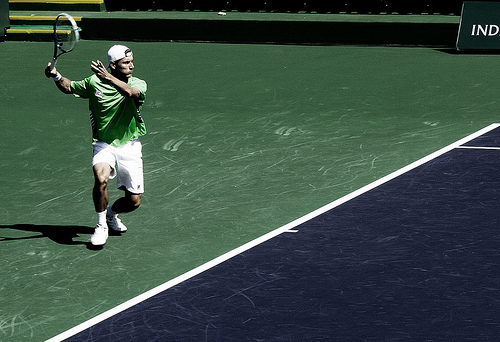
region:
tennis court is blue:
[290, 247, 488, 331]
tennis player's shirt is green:
[71, 67, 174, 137]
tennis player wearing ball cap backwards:
[95, 39, 145, 114]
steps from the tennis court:
[5, 6, 95, 47]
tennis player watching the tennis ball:
[88, 36, 166, 218]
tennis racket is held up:
[22, 0, 91, 102]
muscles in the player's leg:
[87, 158, 114, 194]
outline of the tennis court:
[223, 139, 497, 247]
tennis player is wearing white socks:
[78, 203, 165, 281]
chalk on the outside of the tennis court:
[165, 94, 355, 196]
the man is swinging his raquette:
[19, 12, 181, 270]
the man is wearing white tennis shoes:
[76, 189, 148, 260]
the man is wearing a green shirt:
[61, 33, 166, 148]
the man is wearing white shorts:
[73, 120, 155, 196]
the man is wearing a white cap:
[88, 40, 162, 67]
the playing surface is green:
[193, 76, 345, 136]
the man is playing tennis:
[32, 10, 200, 262]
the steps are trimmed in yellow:
[1, 8, 71, 48]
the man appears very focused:
[43, 40, 166, 280]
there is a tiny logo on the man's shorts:
[118, 178, 160, 195]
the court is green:
[183, 57, 435, 180]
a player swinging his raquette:
[24, 11, 200, 310]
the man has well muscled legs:
[81, 141, 151, 253]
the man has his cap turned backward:
[107, 31, 182, 80]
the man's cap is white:
[102, 37, 134, 85]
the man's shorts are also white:
[71, 120, 187, 212]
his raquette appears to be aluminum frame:
[28, 7, 84, 83]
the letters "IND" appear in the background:
[446, 24, 497, 39]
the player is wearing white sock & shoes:
[63, 204, 185, 289]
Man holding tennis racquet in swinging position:
[43, 13, 150, 255]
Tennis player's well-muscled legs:
[81, 164, 145, 251]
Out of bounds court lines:
[420, 128, 481, 163]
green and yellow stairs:
[5, 11, 82, 38]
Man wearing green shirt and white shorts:
[83, 40, 151, 255]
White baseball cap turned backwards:
[99, 40, 134, 67]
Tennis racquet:
[44, 13, 79, 78]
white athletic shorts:
[89, 136, 147, 198]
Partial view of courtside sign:
[458, 2, 498, 52]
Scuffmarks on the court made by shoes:
[163, 116, 316, 174]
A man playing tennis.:
[26, 7, 173, 262]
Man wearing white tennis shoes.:
[84, 218, 154, 255]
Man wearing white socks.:
[88, 203, 133, 225]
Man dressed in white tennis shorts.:
[87, 134, 156, 201]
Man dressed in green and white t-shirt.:
[71, 71, 164, 138]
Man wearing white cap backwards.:
[98, 41, 146, 68]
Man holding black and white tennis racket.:
[36, 1, 90, 91]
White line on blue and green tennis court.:
[133, 218, 455, 324]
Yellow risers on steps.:
[6, 1, 88, 38]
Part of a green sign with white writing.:
[448, 3, 498, 53]